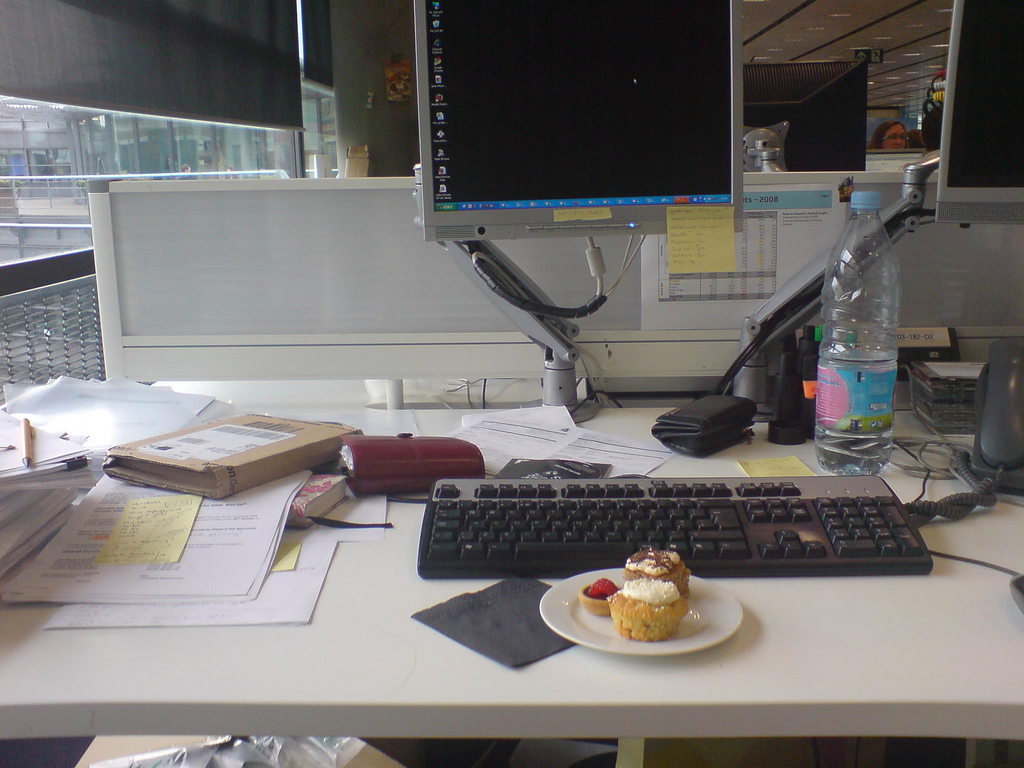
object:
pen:
[20, 418, 36, 468]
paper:
[0, 410, 95, 575]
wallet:
[651, 393, 758, 458]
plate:
[539, 568, 745, 657]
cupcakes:
[577, 549, 690, 642]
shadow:
[0, 603, 60, 660]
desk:
[0, 380, 1024, 742]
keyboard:
[417, 474, 934, 579]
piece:
[584, 578, 619, 600]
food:
[580, 578, 624, 617]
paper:
[0, 469, 337, 629]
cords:
[433, 240, 595, 423]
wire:
[925, 549, 1024, 579]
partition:
[80, 178, 1024, 380]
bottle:
[813, 189, 900, 477]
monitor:
[414, 0, 742, 242]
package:
[101, 414, 363, 501]